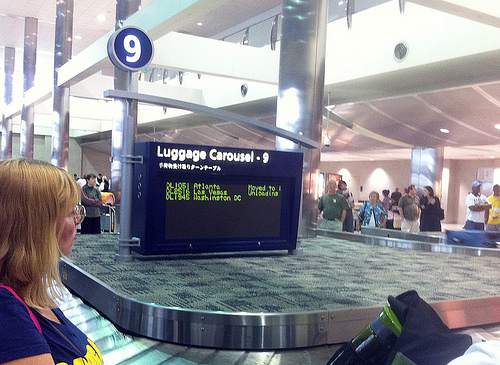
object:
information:
[163, 182, 280, 203]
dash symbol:
[256, 156, 261, 160]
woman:
[356, 190, 386, 228]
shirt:
[1, 284, 103, 364]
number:
[261, 152, 271, 163]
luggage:
[437, 228, 499, 246]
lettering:
[70, 337, 104, 364]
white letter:
[156, 146, 166, 156]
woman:
[0, 157, 103, 364]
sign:
[141, 142, 303, 256]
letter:
[192, 149, 199, 162]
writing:
[154, 145, 255, 162]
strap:
[1, 283, 42, 333]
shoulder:
[0, 280, 20, 302]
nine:
[121, 32, 141, 63]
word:
[154, 142, 206, 161]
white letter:
[179, 148, 184, 164]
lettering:
[160, 182, 286, 201]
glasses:
[67, 203, 87, 223]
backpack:
[326, 290, 472, 364]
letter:
[186, 149, 194, 161]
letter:
[164, 147, 171, 159]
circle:
[106, 27, 154, 72]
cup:
[348, 303, 402, 364]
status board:
[149, 141, 303, 253]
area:
[61, 234, 498, 314]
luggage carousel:
[40, 225, 500, 365]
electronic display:
[129, 141, 305, 256]